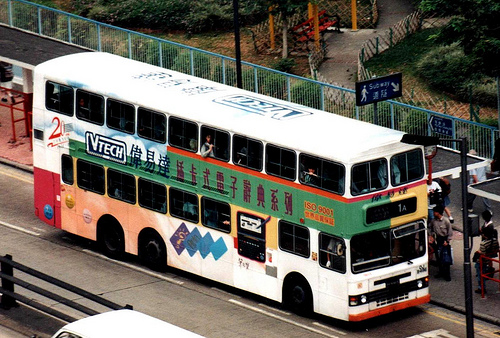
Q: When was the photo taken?
A: Daytime.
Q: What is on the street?
A: A bus.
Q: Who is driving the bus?
A: A driver.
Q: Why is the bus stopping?
A: People are boarding.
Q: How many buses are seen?
A: One.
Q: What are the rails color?
A: Blue.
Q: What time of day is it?
A: Evening.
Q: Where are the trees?
A: In the back.